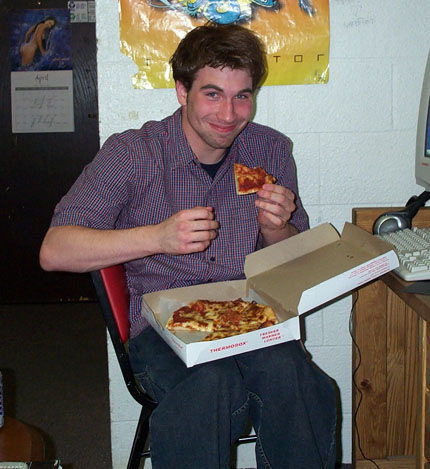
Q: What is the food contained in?
A: Box.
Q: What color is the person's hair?
A: Brown.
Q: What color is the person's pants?
A: Blue.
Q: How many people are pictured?
A: One.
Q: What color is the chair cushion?
A: Red.